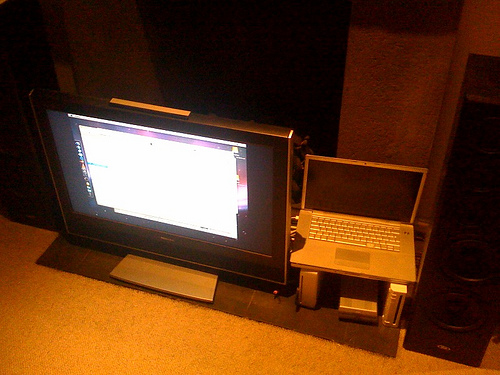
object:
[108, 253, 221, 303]
base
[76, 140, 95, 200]
toolbar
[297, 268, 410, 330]
mount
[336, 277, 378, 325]
track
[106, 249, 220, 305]
bezel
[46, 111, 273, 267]
screen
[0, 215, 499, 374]
floor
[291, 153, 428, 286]
laptop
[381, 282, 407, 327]
hard drive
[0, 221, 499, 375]
carpet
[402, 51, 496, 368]
speaker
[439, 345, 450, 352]
logo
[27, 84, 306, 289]
rim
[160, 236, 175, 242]
logo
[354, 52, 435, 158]
wall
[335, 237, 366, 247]
key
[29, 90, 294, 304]
television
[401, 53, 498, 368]
tower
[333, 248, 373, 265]
mouse pad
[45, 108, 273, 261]
monitor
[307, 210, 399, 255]
keyboard